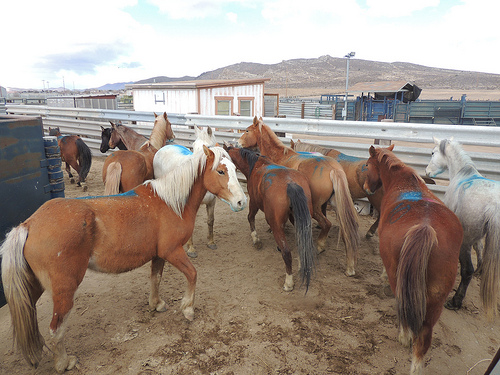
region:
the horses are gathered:
[92, 116, 492, 331]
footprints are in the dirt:
[219, 250, 319, 325]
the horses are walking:
[264, 252, 368, 349]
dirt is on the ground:
[261, 312, 422, 374]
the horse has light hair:
[5, 240, 30, 334]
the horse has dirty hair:
[292, 201, 360, 361]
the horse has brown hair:
[392, 263, 487, 373]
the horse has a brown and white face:
[194, 140, 345, 358]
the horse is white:
[436, 143, 483, 215]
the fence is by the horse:
[266, 113, 431, 196]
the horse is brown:
[360, 148, 470, 368]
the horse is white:
[432, 141, 497, 276]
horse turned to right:
[3, 137, 267, 374]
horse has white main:
[144, 138, 232, 218]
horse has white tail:
[3, 215, 59, 365]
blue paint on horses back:
[74, 185, 143, 216]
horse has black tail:
[283, 175, 330, 297]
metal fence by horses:
[3, 88, 498, 192]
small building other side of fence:
[124, 67, 289, 136]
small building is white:
[127, 65, 272, 137]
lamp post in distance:
[338, 44, 365, 103]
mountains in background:
[36, 39, 498, 110]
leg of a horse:
[46, 310, 76, 372]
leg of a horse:
[143, 259, 169, 329]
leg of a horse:
[182, 245, 222, 305]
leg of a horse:
[198, 190, 228, 253]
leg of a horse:
[238, 198, 268, 269]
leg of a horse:
[273, 215, 289, 284]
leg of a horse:
[307, 206, 338, 267]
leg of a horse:
[337, 210, 359, 280]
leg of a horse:
[391, 280, 450, 354]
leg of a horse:
[444, 243, 479, 323]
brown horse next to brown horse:
[1, 143, 247, 372]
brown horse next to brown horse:
[44, 124, 94, 190]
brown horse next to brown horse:
[101, 112, 176, 195]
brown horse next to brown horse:
[98, 126, 128, 153]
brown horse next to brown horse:
[107, 121, 149, 150]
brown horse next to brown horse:
[215, 143, 317, 293]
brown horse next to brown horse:
[230, 114, 362, 279]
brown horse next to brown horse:
[287, 135, 384, 240]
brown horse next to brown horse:
[361, 142, 465, 374]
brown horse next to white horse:
[424, 134, 498, 314]